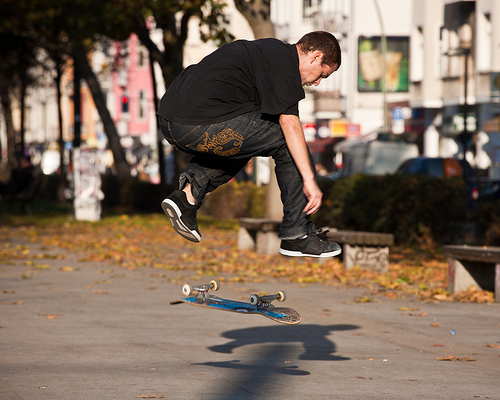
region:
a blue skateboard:
[129, 267, 336, 347]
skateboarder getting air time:
[149, 23, 372, 271]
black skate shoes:
[132, 175, 362, 267]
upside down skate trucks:
[161, 266, 307, 298]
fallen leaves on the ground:
[367, 243, 492, 313]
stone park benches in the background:
[219, 207, 413, 280]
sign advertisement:
[353, 35, 427, 105]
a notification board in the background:
[65, 115, 110, 241]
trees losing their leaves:
[0, 8, 155, 274]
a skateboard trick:
[144, 17, 385, 332]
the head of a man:
[294, 27, 344, 92]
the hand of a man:
[302, 178, 324, 215]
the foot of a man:
[278, 227, 347, 259]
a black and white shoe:
[158, 187, 206, 244]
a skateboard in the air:
[166, 276, 303, 326]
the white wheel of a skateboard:
[176, 280, 195, 297]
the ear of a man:
[308, 46, 328, 63]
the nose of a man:
[311, 75, 321, 85]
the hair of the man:
[295, 27, 346, 72]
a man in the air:
[150, 26, 354, 259]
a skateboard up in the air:
[166, 271, 291, 336]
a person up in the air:
[138, 20, 355, 264]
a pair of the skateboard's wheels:
[240, 281, 288, 302]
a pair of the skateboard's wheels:
[182, 280, 222, 291]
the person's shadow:
[204, 303, 357, 388]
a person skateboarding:
[153, 28, 345, 335]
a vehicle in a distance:
[382, 152, 467, 192]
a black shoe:
[280, 227, 344, 263]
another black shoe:
[152, 180, 214, 250]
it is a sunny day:
[1, 2, 498, 398]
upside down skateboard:
[163, 267, 328, 351]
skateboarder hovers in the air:
[153, 21, 347, 269]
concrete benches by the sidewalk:
[332, 223, 498, 303]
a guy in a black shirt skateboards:
[150, 25, 362, 274]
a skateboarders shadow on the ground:
[193, 307, 376, 383]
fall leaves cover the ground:
[15, 209, 165, 274]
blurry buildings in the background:
[5, 32, 152, 220]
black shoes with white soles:
[144, 182, 389, 279]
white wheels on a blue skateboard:
[162, 275, 317, 346]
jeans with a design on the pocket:
[155, 111, 248, 161]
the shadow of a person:
[194, 301, 359, 381]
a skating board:
[163, 272, 312, 328]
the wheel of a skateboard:
[248, 290, 261, 303]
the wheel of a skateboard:
[276, 288, 285, 303]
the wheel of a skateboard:
[181, 282, 191, 296]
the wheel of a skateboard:
[210, 277, 219, 289]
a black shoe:
[161, 187, 209, 252]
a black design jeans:
[151, 102, 313, 243]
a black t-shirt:
[157, 32, 309, 123]